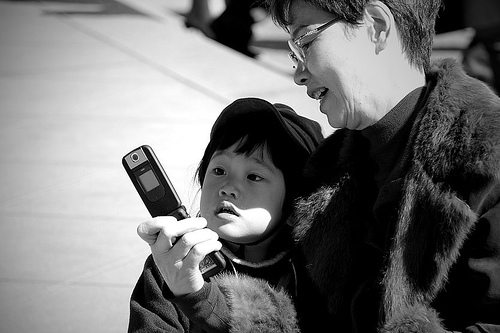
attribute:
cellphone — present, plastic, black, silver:
[115, 145, 227, 280]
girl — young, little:
[128, 97, 331, 332]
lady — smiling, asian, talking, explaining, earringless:
[262, 2, 496, 331]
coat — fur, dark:
[272, 56, 500, 329]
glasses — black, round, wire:
[286, 8, 381, 69]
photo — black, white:
[2, 1, 500, 332]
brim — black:
[212, 99, 293, 147]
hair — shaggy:
[191, 135, 287, 186]